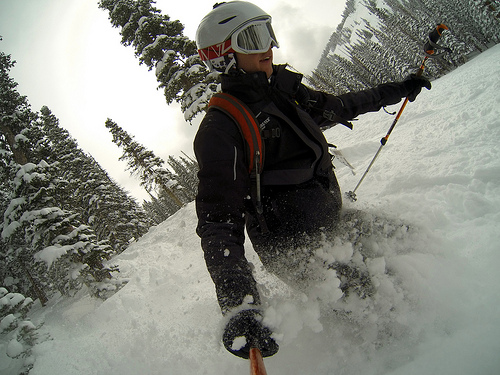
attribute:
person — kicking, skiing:
[193, 2, 431, 358]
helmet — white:
[194, 4, 270, 64]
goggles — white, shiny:
[231, 22, 278, 53]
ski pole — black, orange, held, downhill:
[344, 21, 446, 204]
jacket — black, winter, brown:
[195, 72, 399, 274]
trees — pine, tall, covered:
[0, 0, 198, 303]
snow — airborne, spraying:
[259, 210, 383, 316]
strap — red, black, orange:
[211, 96, 264, 170]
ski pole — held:
[249, 345, 268, 373]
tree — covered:
[108, 117, 185, 208]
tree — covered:
[99, 6, 215, 119]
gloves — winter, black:
[217, 73, 435, 360]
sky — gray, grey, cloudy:
[0, 0, 334, 193]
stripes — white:
[230, 149, 240, 188]